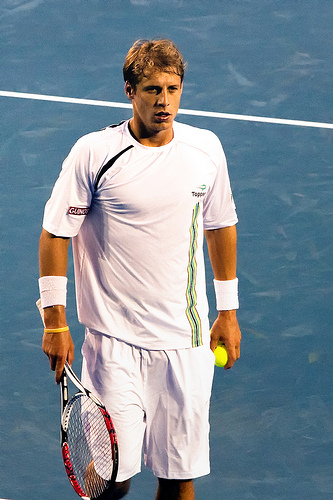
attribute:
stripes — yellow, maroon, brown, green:
[182, 201, 205, 352]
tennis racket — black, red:
[34, 297, 118, 499]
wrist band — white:
[212, 275, 240, 311]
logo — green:
[193, 180, 209, 193]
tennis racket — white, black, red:
[23, 323, 149, 499]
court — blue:
[238, 93, 297, 185]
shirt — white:
[38, 113, 243, 351]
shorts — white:
[80, 328, 215, 480]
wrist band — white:
[204, 260, 244, 348]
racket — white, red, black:
[34, 266, 126, 489]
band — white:
[210, 274, 241, 310]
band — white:
[39, 273, 68, 306]